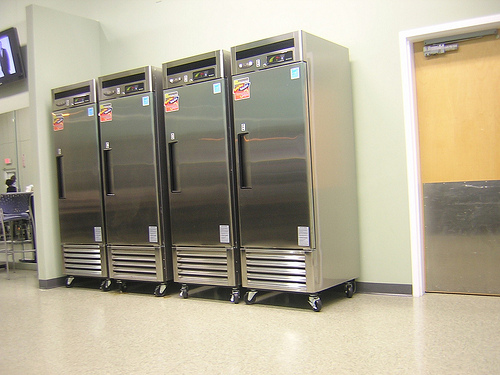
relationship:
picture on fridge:
[230, 74, 253, 104] [231, 31, 361, 312]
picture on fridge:
[162, 87, 182, 115] [157, 47, 239, 301]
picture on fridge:
[97, 103, 117, 127] [95, 66, 172, 296]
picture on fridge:
[51, 114, 62, 134] [49, 77, 111, 290]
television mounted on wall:
[0, 28, 25, 86] [1, 13, 31, 265]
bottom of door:
[419, 179, 499, 295] [412, 21, 497, 296]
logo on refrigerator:
[287, 63, 300, 81] [226, 26, 361, 313]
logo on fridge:
[210, 77, 222, 96] [50, 31, 362, 293]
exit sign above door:
[0, 156, 16, 168] [2, 166, 22, 200]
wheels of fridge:
[64, 278, 354, 312] [231, 31, 361, 312]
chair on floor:
[0, 186, 30, 277] [4, 263, 484, 368]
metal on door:
[411, 183, 499, 304] [409, 25, 484, 295]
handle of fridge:
[232, 126, 254, 194] [231, 31, 361, 312]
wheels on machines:
[62, 272, 359, 308] [47, 28, 363, 293]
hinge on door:
[420, 38, 467, 59] [412, 21, 497, 296]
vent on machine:
[60, 242, 107, 275] [43, 74, 110, 286]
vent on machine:
[108, 242, 159, 281] [91, 61, 170, 296]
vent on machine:
[173, 247, 230, 280] [153, 45, 244, 302]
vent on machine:
[241, 248, 306, 290] [221, 26, 363, 310]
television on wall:
[1, 25, 25, 82] [1, 15, 26, 97]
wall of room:
[1, 15, 26, 97] [1, 25, 112, 297]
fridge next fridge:
[50, 31, 362, 293] [50, 31, 362, 293]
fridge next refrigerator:
[50, 31, 362, 293] [226, 26, 361, 313]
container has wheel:
[229, 28, 359, 300] [306, 297, 323, 311]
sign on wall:
[1, 153, 13, 171] [92, 12, 262, 37]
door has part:
[231, 60, 312, 250] [262, 145, 271, 165]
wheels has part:
[64, 278, 354, 312] [306, 300, 315, 303]